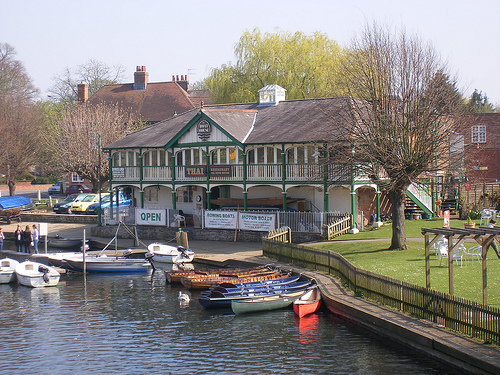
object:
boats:
[165, 264, 323, 321]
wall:
[2, 230, 499, 375]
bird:
[178, 292, 190, 308]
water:
[1, 256, 499, 374]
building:
[102, 86, 434, 232]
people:
[1, 225, 40, 254]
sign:
[133, 208, 168, 227]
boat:
[293, 285, 321, 318]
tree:
[300, 15, 487, 252]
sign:
[184, 165, 232, 179]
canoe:
[232, 289, 306, 314]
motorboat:
[147, 241, 194, 265]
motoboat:
[63, 254, 157, 274]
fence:
[261, 224, 500, 348]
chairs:
[430, 236, 485, 269]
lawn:
[298, 219, 500, 346]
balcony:
[111, 163, 388, 182]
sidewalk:
[2, 220, 499, 374]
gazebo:
[424, 224, 500, 325]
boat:
[17, 259, 61, 287]